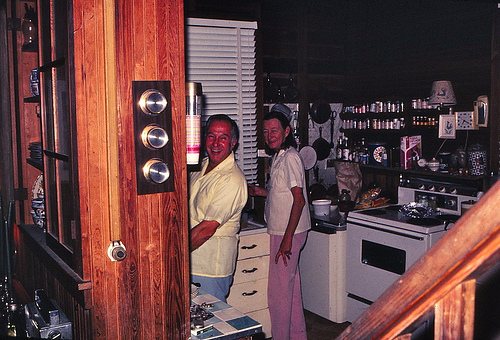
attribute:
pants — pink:
[267, 229, 310, 338]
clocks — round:
[133, 85, 177, 195]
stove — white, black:
[346, 205, 458, 323]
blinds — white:
[188, 17, 261, 213]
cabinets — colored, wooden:
[224, 232, 273, 338]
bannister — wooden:
[335, 180, 500, 338]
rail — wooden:
[332, 180, 498, 339]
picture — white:
[439, 114, 457, 139]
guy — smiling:
[186, 113, 250, 306]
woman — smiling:
[249, 113, 313, 339]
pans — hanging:
[310, 84, 331, 123]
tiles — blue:
[189, 284, 264, 339]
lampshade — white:
[429, 79, 459, 106]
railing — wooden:
[335, 176, 498, 339]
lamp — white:
[427, 79, 458, 115]